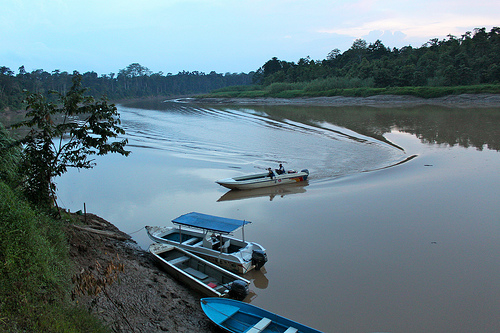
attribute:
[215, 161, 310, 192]
boat — white, long, small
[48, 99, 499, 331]
water — calm, rippled, here, brown, muddy, peaceful, tranquil, serene, even tempered, mellow, subdued, placid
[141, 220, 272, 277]
boat — blue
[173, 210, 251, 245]
canopy — blue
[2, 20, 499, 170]
trees — here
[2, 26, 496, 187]
leaves — green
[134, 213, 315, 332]
boats — together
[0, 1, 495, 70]
sky — clear